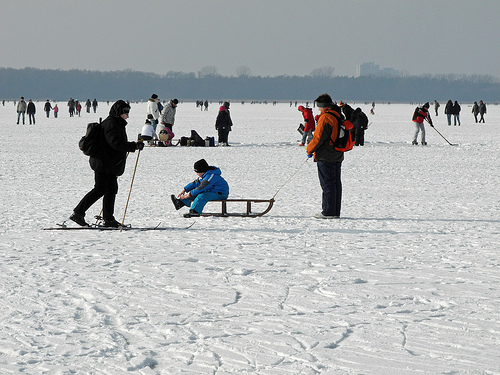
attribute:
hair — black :
[107, 97, 125, 122]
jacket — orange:
[302, 108, 347, 161]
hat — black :
[420, 97, 438, 110]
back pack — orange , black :
[332, 116, 358, 153]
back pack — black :
[77, 121, 104, 156]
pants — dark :
[310, 152, 347, 222]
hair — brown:
[311, 93, 333, 103]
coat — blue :
[182, 166, 229, 215]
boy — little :
[169, 160, 228, 217]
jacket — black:
[84, 114, 137, 178]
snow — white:
[0, 100, 500, 373]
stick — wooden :
[427, 125, 463, 151]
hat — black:
[188, 157, 211, 169]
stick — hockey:
[427, 119, 460, 154]